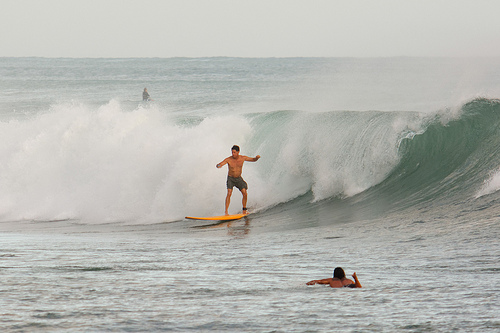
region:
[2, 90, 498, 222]
Large breaking ocean wave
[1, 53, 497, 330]
Ocean with wave breaking on beach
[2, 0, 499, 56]
Pale blue sky above horizon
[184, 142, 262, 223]
Male surfer riding surfboard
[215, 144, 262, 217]
Dark-haired man in swim trunks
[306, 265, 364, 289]
Person with shoulder-length hair floating in water.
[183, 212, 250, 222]
Bright yellow surfboard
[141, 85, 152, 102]
Person in the water barely visible in the distance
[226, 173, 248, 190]
Swim trunks worn by surfer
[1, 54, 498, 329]
Large body of water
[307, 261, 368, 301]
person swimming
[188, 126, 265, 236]
man surfing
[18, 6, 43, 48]
white clouds in blue sky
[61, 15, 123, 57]
white clouds in blue sky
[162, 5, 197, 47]
white clouds in blue sky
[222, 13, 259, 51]
white clouds in blue sky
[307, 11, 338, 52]
white clouds in blue sky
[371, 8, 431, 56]
white clouds in blue sky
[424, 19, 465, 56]
white clouds in blue sky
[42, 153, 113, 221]
white and green waves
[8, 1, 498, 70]
The sky is cloudy.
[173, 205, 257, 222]
The surf board is yellow.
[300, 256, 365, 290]
The man is swimming.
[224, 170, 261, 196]
He has gray shorts on.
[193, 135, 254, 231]
He is surfing.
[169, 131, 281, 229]
He is standing on the board.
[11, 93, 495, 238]
The wave is splashing.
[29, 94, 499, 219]
The wave is large.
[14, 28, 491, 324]
They are in the ocean.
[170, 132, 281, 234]
He is balancing.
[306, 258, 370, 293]
person swimming in the ocean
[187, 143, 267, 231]
man surfing in the ocean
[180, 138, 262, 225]
man on yellow surfboard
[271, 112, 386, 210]
large wave breaking in the ocean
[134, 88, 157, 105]
person behind the large wave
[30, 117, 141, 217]
ocean water spraying up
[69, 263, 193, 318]
calm ocean water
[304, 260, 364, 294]
person with foot in the air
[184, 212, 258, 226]
yellow surfboard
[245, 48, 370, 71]
horizon line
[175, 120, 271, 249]
Man on a surfboard.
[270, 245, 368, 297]
Person in the water.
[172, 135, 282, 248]
Person on a yellow surfboard.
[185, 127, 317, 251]
Man in swim trunks.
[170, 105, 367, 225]
White spray on the water.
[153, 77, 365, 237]
Wave on the ocean.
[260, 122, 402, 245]
Gray and blue ocean.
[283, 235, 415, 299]
Person with dark hair.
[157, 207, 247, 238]
Yellow surf board on the water.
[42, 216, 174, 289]
Ripples in the waves.